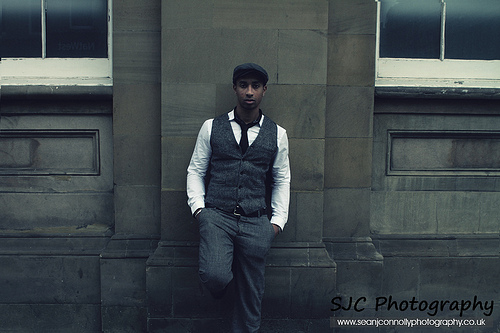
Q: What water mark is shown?
A: SJC Photography.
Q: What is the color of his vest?
A: Grey.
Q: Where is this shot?
A: Street.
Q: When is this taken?
A: Daytime.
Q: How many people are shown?
A: 1.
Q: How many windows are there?
A: 2.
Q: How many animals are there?
A: 0.